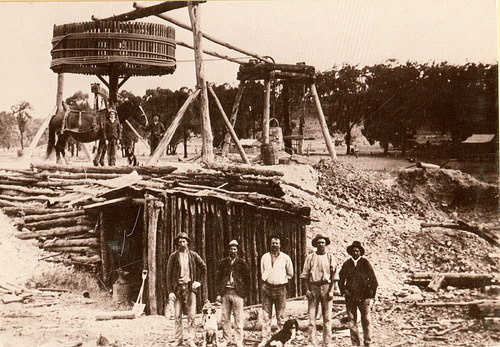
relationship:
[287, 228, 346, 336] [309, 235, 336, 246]
man has hat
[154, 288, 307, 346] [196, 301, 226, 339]
dog has coat